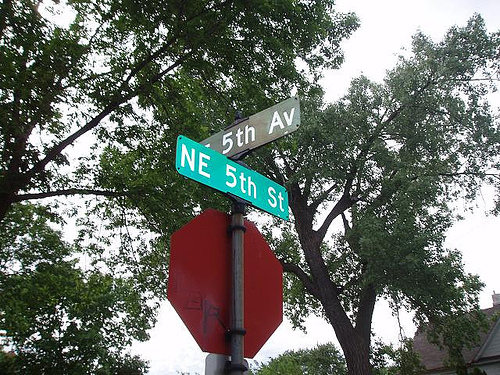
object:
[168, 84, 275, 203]
sign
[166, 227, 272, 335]
sign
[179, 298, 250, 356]
graffiti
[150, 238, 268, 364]
back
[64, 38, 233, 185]
branches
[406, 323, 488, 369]
roof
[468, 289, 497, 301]
chimney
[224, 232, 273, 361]
pole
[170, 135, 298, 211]
lettering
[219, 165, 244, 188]
number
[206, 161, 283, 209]
5th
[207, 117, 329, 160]
5th ave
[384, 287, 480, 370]
home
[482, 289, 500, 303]
bucket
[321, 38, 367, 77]
light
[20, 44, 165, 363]
tree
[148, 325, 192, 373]
sky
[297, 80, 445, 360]
tree